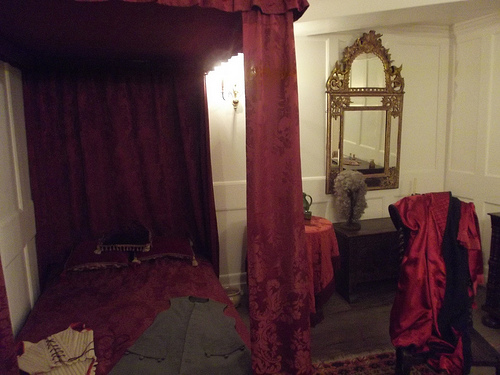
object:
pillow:
[97, 232, 152, 252]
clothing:
[108, 295, 255, 375]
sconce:
[232, 83, 239, 112]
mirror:
[323, 29, 405, 196]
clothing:
[16, 325, 95, 374]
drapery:
[21, 63, 218, 292]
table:
[302, 215, 341, 329]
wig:
[334, 168, 368, 224]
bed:
[0, 236, 256, 375]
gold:
[386, 91, 404, 94]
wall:
[447, 16, 499, 289]